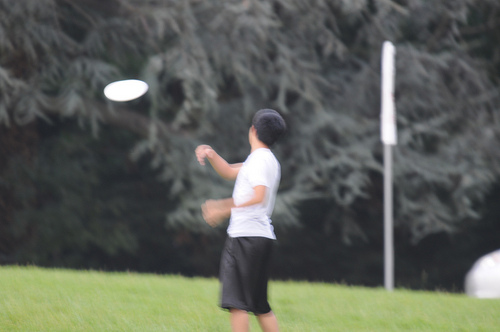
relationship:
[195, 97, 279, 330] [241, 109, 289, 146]
boy has hair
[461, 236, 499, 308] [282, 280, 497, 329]
rock on grass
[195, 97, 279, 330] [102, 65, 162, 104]
boy threw frisbee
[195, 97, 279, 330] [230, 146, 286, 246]
boy has shirt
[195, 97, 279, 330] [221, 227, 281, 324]
boy has shorts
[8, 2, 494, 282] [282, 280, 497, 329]
foliage surrounds grass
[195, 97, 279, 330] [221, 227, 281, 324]
boy in shorts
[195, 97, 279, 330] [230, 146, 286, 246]
boy in shirt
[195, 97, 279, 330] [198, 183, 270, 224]
boy has arm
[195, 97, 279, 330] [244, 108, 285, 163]
boy has head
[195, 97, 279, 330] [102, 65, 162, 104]
boy throwing frisbee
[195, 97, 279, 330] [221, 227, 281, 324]
boy wearing shorts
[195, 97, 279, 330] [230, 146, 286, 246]
boy wearing shirt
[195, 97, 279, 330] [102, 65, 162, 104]
boy playing frisbee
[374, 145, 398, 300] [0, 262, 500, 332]
pole in grass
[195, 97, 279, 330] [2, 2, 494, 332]
boy in park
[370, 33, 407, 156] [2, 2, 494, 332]
sign in park